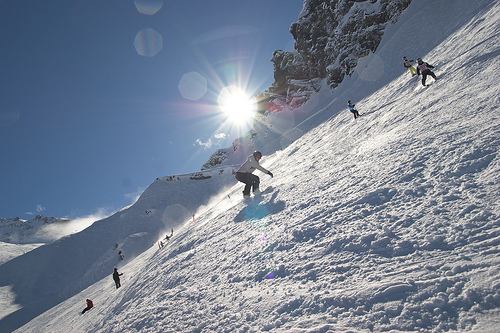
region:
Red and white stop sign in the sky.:
[6, 248, 20, 318]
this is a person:
[235, 149, 275, 197]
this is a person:
[343, 95, 361, 122]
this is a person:
[414, 50, 437, 88]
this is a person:
[400, 47, 416, 91]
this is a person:
[78, 295, 101, 318]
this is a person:
[108, 262, 126, 289]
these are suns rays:
[208, 80, 269, 142]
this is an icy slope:
[168, 255, 243, 331]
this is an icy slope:
[284, 200, 405, 331]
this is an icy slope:
[416, 95, 498, 258]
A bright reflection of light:
[211, 81, 261, 129]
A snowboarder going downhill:
[230, 148, 275, 205]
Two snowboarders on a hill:
[399, 54, 436, 86]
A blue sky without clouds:
[6, 5, 215, 164]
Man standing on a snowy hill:
[111, 265, 125, 288]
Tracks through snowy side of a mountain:
[286, 153, 486, 310]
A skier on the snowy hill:
[346, 98, 360, 119]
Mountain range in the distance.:
[1, 210, 86, 245]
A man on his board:
[236, 149, 275, 201]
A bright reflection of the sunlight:
[215, 82, 257, 130]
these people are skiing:
[26, 16, 482, 272]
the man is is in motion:
[198, 129, 287, 200]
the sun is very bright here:
[165, 64, 303, 121]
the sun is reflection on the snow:
[135, 233, 400, 326]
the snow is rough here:
[172, 208, 482, 316]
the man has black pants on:
[217, 159, 283, 201]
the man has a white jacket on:
[230, 152, 291, 165]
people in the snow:
[205, 40, 460, 265]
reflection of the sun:
[109, 18, 267, 141]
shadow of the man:
[217, 191, 295, 221]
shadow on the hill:
[37, 220, 146, 278]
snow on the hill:
[257, 11, 370, 80]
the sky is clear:
[64, 105, 143, 161]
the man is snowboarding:
[225, 138, 285, 214]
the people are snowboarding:
[410, 54, 457, 89]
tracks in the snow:
[355, 198, 485, 312]